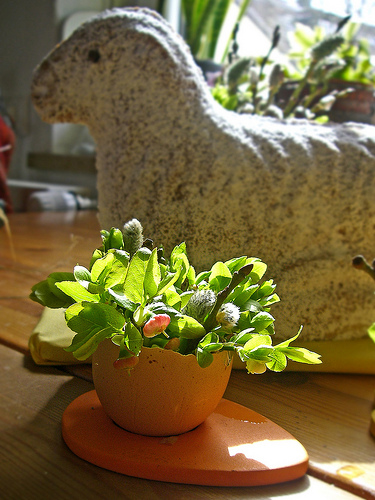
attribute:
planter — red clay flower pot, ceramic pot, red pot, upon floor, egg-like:
[90, 335, 231, 437]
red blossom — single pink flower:
[144, 309, 173, 343]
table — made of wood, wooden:
[4, 213, 370, 470]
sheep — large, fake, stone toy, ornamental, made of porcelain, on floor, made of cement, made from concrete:
[33, 10, 373, 345]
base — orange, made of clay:
[61, 391, 310, 480]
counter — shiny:
[5, 220, 92, 372]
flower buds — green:
[186, 283, 239, 326]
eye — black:
[88, 46, 104, 65]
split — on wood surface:
[308, 467, 374, 499]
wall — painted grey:
[4, 4, 57, 152]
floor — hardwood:
[5, 353, 370, 489]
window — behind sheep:
[229, 6, 374, 73]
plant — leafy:
[299, 17, 374, 86]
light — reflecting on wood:
[236, 442, 372, 500]